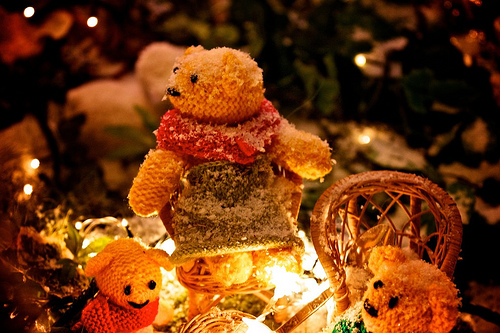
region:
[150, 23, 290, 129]
An orange teddy bear head.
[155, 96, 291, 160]
Teddy bear wearing a red scarf.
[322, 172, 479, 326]
Teddy bear sitting on a wicker chair.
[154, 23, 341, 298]
Bear with the red scarf sitting in a chair.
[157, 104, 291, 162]
Snow on the stuffed animals scarf.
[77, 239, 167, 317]
Bear head with a smiling face.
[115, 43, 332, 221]
The teddy bear was knit by hand.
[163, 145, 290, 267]
Teddy wearing a green blanket.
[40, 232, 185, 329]
This teddy is not sitting on a chair.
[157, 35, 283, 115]
Teddy bear looking to the side.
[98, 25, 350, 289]
small stuffed bear above others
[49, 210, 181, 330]
small yarn bear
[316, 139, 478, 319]
small wicker chair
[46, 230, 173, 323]
yarn bear wearing red scarf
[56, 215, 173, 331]
yarn bear looking at camera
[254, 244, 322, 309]
christmas light near yarn bears bears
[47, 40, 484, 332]
trio of yarn bears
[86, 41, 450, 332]
yarn bears on display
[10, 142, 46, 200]
christmas lights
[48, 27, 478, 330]
winter themes bear display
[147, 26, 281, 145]
head of a teddy bear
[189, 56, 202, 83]
eye of a teddy bear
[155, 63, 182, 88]
eye of a teddy bear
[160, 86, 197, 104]
nose of a teddy bear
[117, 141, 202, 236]
arm of a teddy bear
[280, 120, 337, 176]
arm of a teddy bear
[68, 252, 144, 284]
ear of a teddy bear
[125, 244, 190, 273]
ear of a teddy bear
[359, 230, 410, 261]
ear of a teddy bear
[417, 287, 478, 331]
ear of a teddy bear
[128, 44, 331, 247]
white crochet animal on ball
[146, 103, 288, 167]
bear is wearing scarf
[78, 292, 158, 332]
orange scarf around bears neck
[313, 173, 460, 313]
wicker chair behind bear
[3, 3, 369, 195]
chrismtas lights shine brightly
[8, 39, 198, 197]
white bear behind bears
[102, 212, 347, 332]
christmas ball under bear is lighted up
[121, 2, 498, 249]
green and white christmas tree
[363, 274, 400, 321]
bear on bottom right has black eyes and nose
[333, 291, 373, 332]
green and white scarf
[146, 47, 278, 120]
the head of a bear doll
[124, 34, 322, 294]
a bear doll decoration piece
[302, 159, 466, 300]
a tiny wicker chair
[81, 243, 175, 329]
a small bear doll with a red shirt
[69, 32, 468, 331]
a group of three bear dolls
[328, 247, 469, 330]
a bear doll wearing a green shirt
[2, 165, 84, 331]
some flower decorations on a table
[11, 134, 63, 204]
tiny white light bulbs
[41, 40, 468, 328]
a decoration piece consisting of bears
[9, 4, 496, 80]
a string of lights hanging